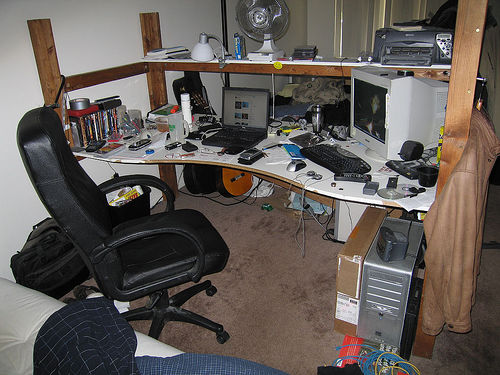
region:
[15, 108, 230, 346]
chair is next to desk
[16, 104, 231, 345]
chair has five wheels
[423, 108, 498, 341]
brown jacket hanging from desk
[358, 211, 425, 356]
cpu under the desk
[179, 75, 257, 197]
guitar is behind desk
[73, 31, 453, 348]
desk has two levels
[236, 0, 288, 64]
fan on top of desk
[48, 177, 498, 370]
carpet in room is brown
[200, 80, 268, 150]
laptop on top of desk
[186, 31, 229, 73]
white lamp clipped on desk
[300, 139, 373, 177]
Keyboard on a desk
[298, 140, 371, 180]
Keyboard is on a desk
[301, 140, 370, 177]
Keyboard on a white desk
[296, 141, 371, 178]
Keyboard is on a white desk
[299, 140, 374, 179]
Black keyboard on a desk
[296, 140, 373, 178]
Black keyboard is on a desk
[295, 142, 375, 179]
Black keyboard on a white desk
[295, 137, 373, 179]
Black keyboard is on a white desk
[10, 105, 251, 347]
Black chair in front of desk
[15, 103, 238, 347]
Black leather chair in front of desk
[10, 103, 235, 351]
Black computer chair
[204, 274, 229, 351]
Two black wheels on chair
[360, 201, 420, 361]
Grey computer modem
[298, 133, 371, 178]
Black computer keyboard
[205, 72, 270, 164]
Small black laptop on desk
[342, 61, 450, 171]
Large white computer monitor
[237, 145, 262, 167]
Black and silver cell phone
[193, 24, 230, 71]
Small silver and white lamp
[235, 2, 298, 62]
Small white and silver fan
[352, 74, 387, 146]
Black computer screen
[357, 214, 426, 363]
Desktop computer sitting on the floor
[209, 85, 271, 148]
Laptop computer sitting on the desk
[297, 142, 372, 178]
Keyboard for desktop computer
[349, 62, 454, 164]
Old CRT computer monitor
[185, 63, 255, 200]
Guitar leaning against the wall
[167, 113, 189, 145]
Drinking mug sitting on the desk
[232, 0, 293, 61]
Small electric fan sitting on a shelf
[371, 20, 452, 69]
Computer printer sitting on a shelf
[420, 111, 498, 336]
Coat hanging from computer desk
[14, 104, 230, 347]
Black leather desk chair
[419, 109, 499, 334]
A brown jacket hanging up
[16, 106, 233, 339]
A large black office chair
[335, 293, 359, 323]
A white label on the side of a package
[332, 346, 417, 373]
A collection of blue and yellow wires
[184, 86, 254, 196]
An orange guitar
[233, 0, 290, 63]
A table fan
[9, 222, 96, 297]
A black bag against the wall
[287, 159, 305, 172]
A computer mouse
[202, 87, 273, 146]
An open laptop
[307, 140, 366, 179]
A black keyboard